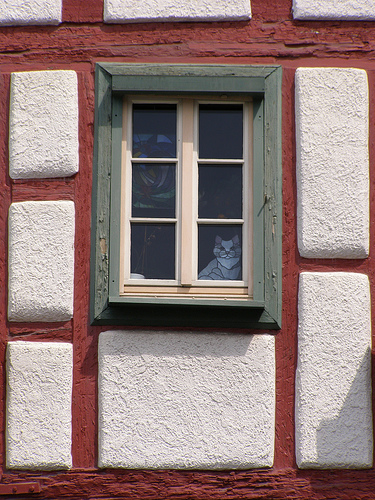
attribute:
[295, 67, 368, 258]
brick — rectangle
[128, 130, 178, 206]
panel — colorful, stained glass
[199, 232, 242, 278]
panel — stained glass, colorful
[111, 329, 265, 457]
stucco — white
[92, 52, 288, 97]
frame — green, wooden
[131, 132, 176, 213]
stained glass — multi-colored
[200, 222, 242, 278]
stained glass — multi-colored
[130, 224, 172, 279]
stained glass — multi-colored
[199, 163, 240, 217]
stained glass — multi-colored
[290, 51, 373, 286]
block — white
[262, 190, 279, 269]
paint — chipped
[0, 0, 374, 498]
wall — white, brown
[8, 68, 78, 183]
square — white, stucco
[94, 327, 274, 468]
square — white, stucco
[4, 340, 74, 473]
square — white, stucco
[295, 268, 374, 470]
square — white, stucco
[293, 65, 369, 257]
square — white, stucco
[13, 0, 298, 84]
wood beam — red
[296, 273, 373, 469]
block — long, white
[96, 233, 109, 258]
paint — missing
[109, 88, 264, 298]
paned window — paned glass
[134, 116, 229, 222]
panes — white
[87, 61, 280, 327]
frame — green, wooden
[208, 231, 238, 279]
eyes — black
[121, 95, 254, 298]
trim — white, tan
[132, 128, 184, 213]
art — colorful, mosaic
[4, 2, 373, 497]
trim — red , wood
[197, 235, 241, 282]
cat pattern — glass, stained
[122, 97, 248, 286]
window — plain, glass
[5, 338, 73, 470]
rectangle — small